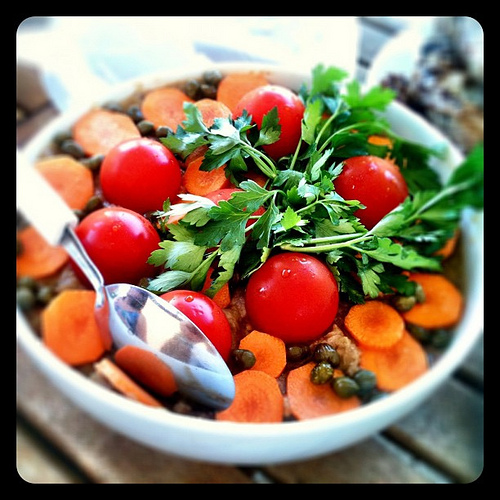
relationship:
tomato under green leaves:
[342, 152, 404, 214] [141, 56, 487, 311]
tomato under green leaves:
[98, 133, 178, 210] [140, 65, 485, 295]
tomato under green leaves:
[68, 205, 164, 284] [140, 65, 485, 295]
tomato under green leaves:
[156, 285, 233, 361] [140, 65, 485, 295]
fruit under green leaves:
[244, 252, 339, 347] [140, 65, 485, 295]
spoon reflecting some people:
[16, 152, 236, 410] [112, 282, 202, 362]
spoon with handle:
[16, 152, 236, 410] [14, 147, 77, 249]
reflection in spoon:
[105, 280, 231, 400] [91, 270, 242, 400]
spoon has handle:
[97, 249, 254, 381] [8, 163, 119, 240]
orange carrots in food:
[344, 300, 403, 350] [16, 71, 484, 423]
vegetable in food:
[359, 335, 427, 390] [16, 71, 484, 423]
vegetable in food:
[396, 275, 461, 328] [16, 71, 484, 423]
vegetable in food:
[214, 369, 285, 423] [16, 71, 484, 423]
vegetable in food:
[143, 87, 195, 129] [16, 71, 484, 423]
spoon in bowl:
[16, 152, 236, 410] [18, 58, 485, 460]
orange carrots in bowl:
[350, 304, 407, 348] [18, 58, 485, 460]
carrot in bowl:
[41, 288, 114, 366] [18, 58, 485, 460]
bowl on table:
[18, 58, 485, 460] [15, 93, 488, 496]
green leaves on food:
[147, 62, 484, 304] [18, 68, 485, 430]